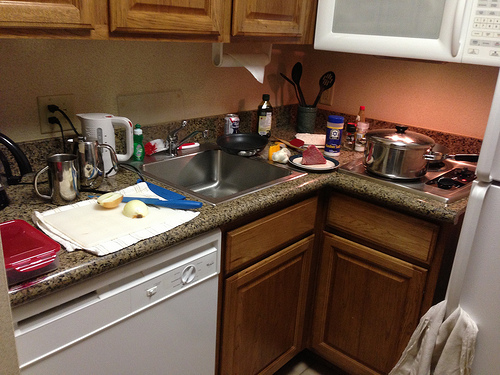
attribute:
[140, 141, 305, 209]
sink — stainless steel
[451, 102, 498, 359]
refrigerator — white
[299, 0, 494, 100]
microwave — white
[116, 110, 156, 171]
soap — green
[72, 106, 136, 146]
pitcher — white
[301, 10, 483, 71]
microwave — white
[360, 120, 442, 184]
pot — silver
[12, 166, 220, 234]
counter — stone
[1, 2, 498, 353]
kitchen — small, cluttered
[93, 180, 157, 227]
onion — sliced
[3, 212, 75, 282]
lid — red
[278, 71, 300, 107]
utensils — black, plastic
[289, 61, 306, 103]
utensils — black, plastic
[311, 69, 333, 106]
utensils — black, plastic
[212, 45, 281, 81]
paper towel — white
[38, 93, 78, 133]
outlet — beige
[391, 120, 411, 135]
knob — black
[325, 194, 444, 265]
drawer — brown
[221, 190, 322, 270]
drawer — brown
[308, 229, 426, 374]
door — brown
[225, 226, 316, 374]
door — brown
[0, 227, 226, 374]
dishwasher — white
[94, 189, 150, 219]
onion — white, sliced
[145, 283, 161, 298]
switch — white